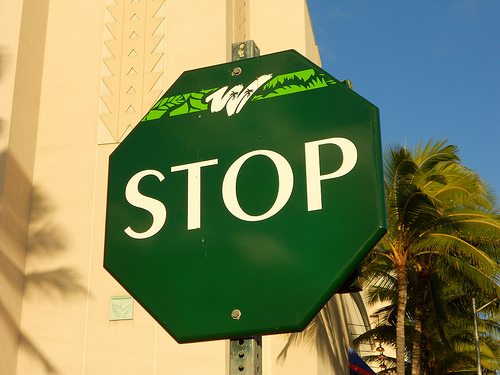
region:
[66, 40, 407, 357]
green octagon sign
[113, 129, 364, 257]
white lettering in all caps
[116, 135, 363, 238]
white lettering that says "STOP"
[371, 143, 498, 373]
tree with long green branches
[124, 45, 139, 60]
tiny right side up triangle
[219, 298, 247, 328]
small silver bolt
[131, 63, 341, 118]
white and green logo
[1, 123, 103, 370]
shadow from the tree on the side of the building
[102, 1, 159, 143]
tan symmetrical design on the side of the building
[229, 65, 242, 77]
tiny bolt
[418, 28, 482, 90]
part of the sky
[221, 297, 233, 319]
part of a bolt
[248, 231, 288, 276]
part of a bolt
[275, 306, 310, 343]
part of an edge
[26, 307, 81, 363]
part of a wall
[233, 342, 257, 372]
part of a post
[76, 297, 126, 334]
part of a line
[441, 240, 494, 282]
part of a tree branches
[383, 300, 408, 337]
part of a stem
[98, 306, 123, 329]
edge of a switch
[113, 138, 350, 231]
the word stop on the sign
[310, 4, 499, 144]
the blue sky above the trees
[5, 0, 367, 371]
the building next to the trees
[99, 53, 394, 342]
a stop sign on the pole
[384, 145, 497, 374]
palm strees next to the building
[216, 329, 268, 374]
the pole the sign is attached to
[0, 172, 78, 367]
the shadow of a tree on the building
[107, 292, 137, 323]
a small picture on the building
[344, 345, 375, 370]
a flag next to the trees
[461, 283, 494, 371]
a light pole standing under the trees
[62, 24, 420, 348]
the stop sign is green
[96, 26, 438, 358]
the word is stop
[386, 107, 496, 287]
this is a palm tree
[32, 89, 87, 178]
the building is pink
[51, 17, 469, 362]
the scene is tropical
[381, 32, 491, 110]
the sky is clear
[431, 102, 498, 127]
the sky is blue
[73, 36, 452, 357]
the stop sign has eight sides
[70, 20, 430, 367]
octagons have eight sides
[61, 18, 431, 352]
the logo has palm trees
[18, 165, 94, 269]
shadow cast on the building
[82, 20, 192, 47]
beautiful design on side of building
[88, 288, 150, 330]
small white sign on building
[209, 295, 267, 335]
small screw in green sign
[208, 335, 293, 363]
large silver sign on post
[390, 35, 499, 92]
crystal clear blue skies overhead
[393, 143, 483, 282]
palm trees by side of building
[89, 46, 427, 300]
large green sign on post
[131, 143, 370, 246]
large bold white words on sign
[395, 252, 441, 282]
coconut on green palm tree